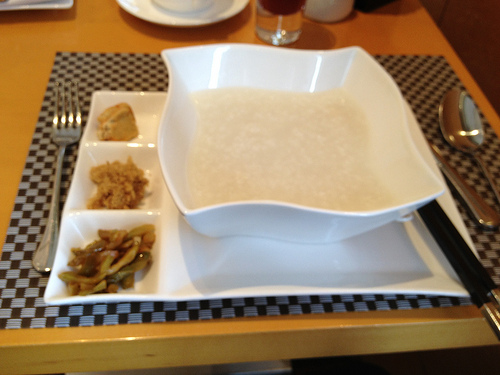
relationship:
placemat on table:
[0, 50, 499, 327] [0, 1, 499, 373]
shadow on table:
[300, 21, 336, 50] [0, 1, 499, 373]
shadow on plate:
[213, 226, 433, 288] [43, 88, 477, 302]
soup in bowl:
[189, 86, 386, 207] [158, 42, 449, 242]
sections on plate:
[51, 91, 165, 301] [43, 88, 477, 302]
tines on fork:
[54, 80, 81, 130] [33, 80, 84, 276]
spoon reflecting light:
[438, 86, 499, 205] [456, 126, 480, 139]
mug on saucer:
[150, 0, 214, 14] [113, 1, 253, 27]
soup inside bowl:
[189, 86, 386, 207] [158, 42, 449, 242]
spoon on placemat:
[438, 86, 499, 205] [0, 50, 499, 327]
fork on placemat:
[33, 80, 84, 276] [0, 50, 499, 327]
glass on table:
[254, 0, 302, 45] [0, 1, 499, 373]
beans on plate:
[58, 223, 157, 293] [43, 88, 477, 302]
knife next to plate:
[428, 131, 498, 230] [43, 88, 477, 302]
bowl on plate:
[158, 42, 449, 242] [43, 88, 477, 302]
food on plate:
[92, 102, 139, 142] [43, 88, 477, 302]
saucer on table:
[113, 1, 253, 27] [0, 1, 499, 373]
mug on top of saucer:
[150, 0, 214, 14] [113, 1, 253, 27]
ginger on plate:
[86, 157, 151, 210] [43, 88, 477, 302]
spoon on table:
[438, 86, 499, 205] [0, 1, 499, 373]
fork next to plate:
[33, 80, 84, 276] [43, 88, 477, 302]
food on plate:
[63, 101, 156, 292] [43, 88, 477, 302]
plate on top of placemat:
[43, 88, 477, 302] [0, 50, 499, 327]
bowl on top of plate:
[158, 42, 449, 242] [43, 88, 477, 302]